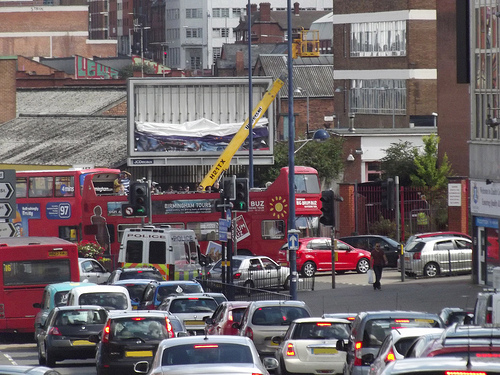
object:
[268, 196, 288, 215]
sun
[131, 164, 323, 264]
bus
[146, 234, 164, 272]
door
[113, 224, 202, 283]
van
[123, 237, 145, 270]
door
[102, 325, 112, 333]
light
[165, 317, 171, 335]
light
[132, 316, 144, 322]
light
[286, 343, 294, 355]
light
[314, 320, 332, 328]
light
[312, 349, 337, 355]
plate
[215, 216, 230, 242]
sign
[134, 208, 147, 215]
light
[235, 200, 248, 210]
light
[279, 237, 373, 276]
car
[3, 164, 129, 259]
bus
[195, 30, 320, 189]
crane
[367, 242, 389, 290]
person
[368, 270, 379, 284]
bag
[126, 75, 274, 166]
billboard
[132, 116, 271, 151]
changed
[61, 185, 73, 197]
peopel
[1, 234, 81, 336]
bus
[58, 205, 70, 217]
number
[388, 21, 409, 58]
windows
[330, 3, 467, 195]
building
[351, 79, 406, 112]
windows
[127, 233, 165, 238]
word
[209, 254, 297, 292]
car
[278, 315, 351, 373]
car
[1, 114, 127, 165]
roof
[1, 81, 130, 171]
building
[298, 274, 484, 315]
sidewalk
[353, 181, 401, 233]
fence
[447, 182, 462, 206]
sign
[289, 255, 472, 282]
street